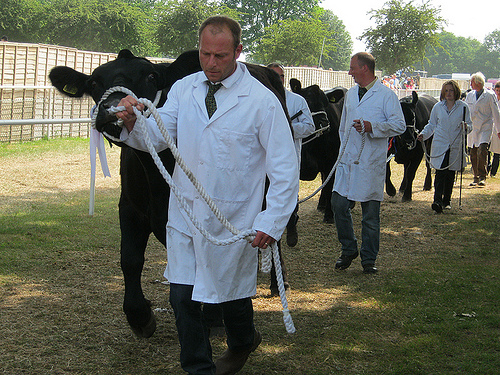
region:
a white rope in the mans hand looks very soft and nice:
[141, 153, 301, 279]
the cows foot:
[118, 297, 154, 349]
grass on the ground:
[398, 285, 453, 328]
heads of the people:
[324, 55, 496, 90]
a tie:
[198, 89, 222, 119]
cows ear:
[41, 55, 91, 107]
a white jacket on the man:
[164, 65, 306, 221]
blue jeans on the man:
[326, 187, 397, 268]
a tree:
[366, 2, 433, 68]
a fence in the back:
[6, 43, 38, 156]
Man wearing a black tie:
[201, 77, 222, 118]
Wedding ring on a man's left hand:
[262, 241, 272, 247]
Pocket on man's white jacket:
[214, 122, 255, 179]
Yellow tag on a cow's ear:
[58, 76, 88, 103]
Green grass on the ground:
[422, 271, 492, 367]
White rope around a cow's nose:
[88, 83, 156, 140]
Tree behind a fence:
[359, 10, 449, 77]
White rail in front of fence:
[6, 114, 108, 134]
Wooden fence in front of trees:
[3, 39, 91, 134]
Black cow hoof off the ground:
[116, 297, 163, 345]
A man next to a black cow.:
[46, 17, 319, 368]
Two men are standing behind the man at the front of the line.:
[272, 36, 413, 272]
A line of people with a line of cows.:
[56, 20, 497, 362]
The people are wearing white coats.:
[112, 15, 497, 342]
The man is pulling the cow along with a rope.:
[81, 83, 292, 304]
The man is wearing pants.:
[320, 180, 392, 276]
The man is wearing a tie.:
[191, 78, 233, 128]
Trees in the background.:
[275, 0, 425, 53]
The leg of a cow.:
[102, 196, 155, 347]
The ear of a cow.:
[42, 59, 88, 102]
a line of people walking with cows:
[51, 25, 497, 370]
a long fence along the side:
[3, 43, 490, 148]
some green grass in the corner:
[358, 262, 498, 373]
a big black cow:
[46, 46, 296, 338]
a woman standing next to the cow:
[420, 75, 474, 207]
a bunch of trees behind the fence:
[0, 2, 499, 77]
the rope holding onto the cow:
[73, 72, 305, 329]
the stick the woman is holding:
[458, 106, 467, 206]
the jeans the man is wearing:
[331, 187, 385, 279]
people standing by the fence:
[382, 70, 419, 85]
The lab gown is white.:
[166, 87, 270, 265]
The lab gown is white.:
[136, 88, 212, 244]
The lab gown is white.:
[206, 136, 274, 253]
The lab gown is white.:
[226, 134, 300, 324]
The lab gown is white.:
[132, 108, 247, 303]